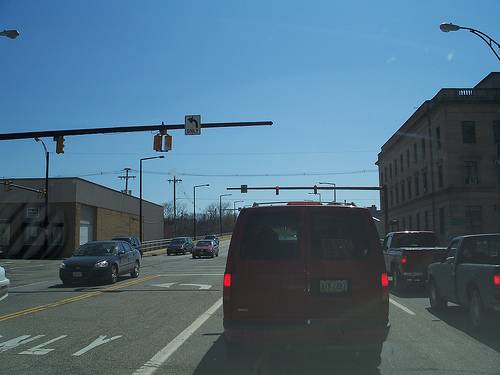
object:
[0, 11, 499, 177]
cloud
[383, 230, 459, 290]
truck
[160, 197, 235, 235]
trees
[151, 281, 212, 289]
arrow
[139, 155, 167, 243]
lamp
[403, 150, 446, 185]
windows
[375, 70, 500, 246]
building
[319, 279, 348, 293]
license tag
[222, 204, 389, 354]
vehicle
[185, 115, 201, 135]
sign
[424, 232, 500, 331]
truck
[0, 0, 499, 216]
sky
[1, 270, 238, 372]
lines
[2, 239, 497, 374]
road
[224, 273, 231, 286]
light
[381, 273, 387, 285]
light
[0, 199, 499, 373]
traffic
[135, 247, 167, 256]
sidewalk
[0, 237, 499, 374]
street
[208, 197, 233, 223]
leaves